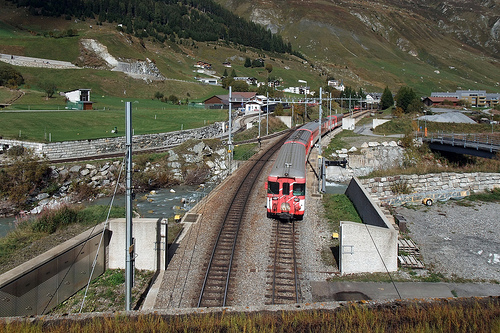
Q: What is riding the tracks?
A: Train.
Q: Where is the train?
A: On the tracks.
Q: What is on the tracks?
A: A red train.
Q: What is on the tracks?
A: An old red train.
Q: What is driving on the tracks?
A: A red train.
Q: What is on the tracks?
A: An old train.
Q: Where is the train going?
A: To its destination.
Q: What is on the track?
A: An old train.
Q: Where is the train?
A: On the track.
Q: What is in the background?
A: A few houses.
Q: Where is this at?
A: An open town.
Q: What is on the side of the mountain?
A: Forest.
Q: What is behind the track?
A: Mountain.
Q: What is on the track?
A: Train.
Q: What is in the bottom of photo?
A: Grass.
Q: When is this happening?
A: During the day time.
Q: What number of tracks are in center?
A: 2.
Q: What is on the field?
A: Buildings.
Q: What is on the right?
A: A gray space.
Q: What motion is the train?
A: Moving.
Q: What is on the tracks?
A: A passenger train.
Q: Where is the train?
A: On the tracks.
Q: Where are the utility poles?
A: Next to the train tracks.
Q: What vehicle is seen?
A: A train.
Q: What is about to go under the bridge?
A: A train.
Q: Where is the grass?
A: On the hillside.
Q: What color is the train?
A: Red.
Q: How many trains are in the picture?
A: One.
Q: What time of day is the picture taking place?
A: Daytime.